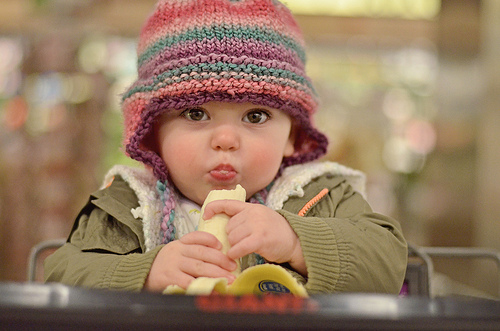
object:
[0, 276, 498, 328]
bar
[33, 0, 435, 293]
child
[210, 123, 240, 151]
nose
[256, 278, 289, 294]
sticker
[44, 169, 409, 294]
jacket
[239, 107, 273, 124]
eye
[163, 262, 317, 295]
peel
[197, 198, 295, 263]
hands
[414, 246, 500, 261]
bar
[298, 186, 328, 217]
zipper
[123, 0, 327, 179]
purple beanie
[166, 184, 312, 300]
banana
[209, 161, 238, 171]
lips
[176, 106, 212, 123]
eye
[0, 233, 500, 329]
cart